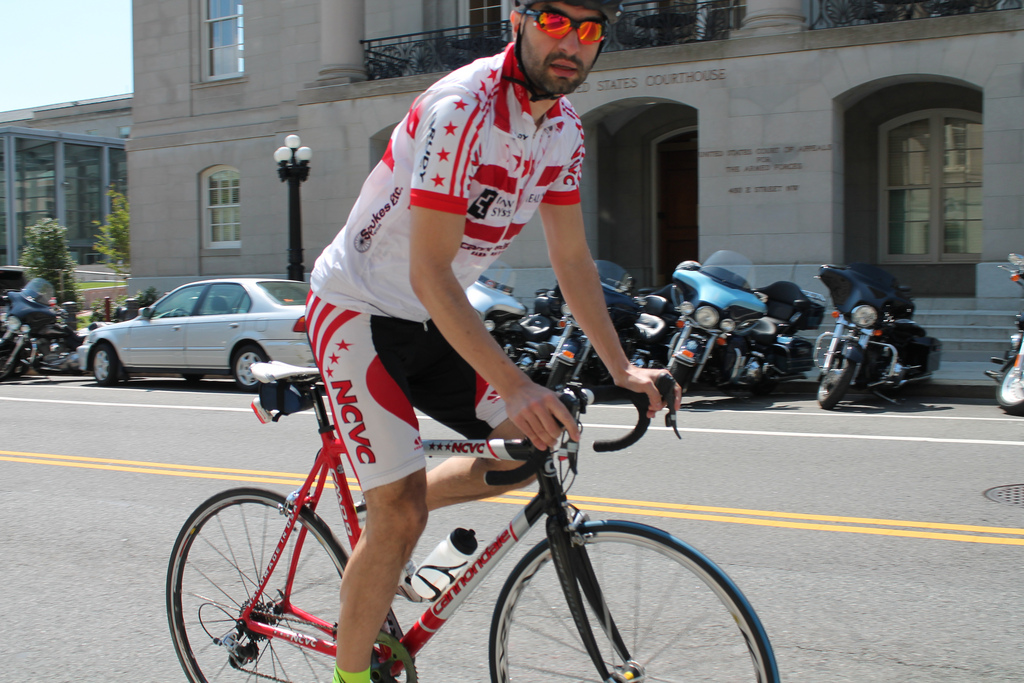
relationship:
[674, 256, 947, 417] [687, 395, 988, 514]
motorcycles parked on street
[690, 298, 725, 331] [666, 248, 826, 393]
headlight on motorcycle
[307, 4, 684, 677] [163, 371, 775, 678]
man on bicycle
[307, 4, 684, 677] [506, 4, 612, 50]
man wearing glasses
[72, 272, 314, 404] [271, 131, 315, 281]
car by lamp pole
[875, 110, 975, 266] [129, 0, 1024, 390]
large window in front of courthouse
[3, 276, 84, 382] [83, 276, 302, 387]
motorcycle front of car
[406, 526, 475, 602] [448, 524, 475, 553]
water bottle with black cap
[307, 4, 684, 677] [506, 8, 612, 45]
man with glasses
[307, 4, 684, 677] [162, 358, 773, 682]
man riding bicycle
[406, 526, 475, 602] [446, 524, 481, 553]
water bottle with black cap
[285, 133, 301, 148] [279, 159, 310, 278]
light on metal pole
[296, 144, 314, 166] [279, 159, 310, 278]
street lamp on metal pole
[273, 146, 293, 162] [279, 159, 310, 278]
light on metal pole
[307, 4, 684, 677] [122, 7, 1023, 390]
man in front of courthouse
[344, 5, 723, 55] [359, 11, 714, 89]
railing on balcony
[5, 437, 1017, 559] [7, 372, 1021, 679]
yellow lines on street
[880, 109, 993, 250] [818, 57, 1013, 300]
window behind arch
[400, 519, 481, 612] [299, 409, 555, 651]
water bottle attached to bicycle frame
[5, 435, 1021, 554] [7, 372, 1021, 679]
line on street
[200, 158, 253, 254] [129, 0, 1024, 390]
window on courthouse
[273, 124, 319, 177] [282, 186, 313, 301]
street lamps on pole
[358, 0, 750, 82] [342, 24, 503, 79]
balcony on balcony